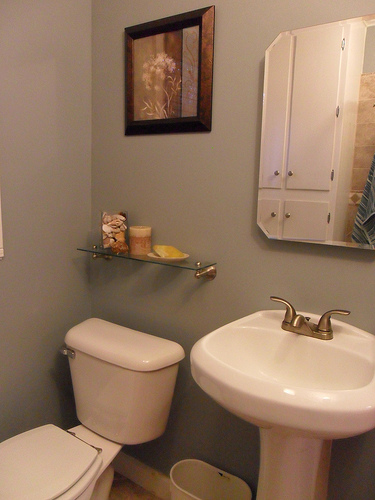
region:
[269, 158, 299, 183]
silver door handle on cabinet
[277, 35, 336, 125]
white cabinet door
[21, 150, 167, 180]
freshly painted white walls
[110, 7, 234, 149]
brown frame on picture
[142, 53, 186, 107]
flowers in the picture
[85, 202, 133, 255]
napkin box on shelf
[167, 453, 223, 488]
white waste basket on ground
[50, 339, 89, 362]
silver handle on toilet bowl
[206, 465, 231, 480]
small black spot on back of waste basket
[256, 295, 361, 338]
gold faucets on porcelain sink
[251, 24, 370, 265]
Mirror on the wall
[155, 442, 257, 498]
Trash can on the floor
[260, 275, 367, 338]
Faucet on the sink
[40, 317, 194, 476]
The toilet is white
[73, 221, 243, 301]
Shelf above the toilet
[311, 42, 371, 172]
Reflection in the mirror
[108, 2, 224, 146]
Picture on the wall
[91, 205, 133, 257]
Shells in a jar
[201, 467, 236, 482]
Stain inside the trash can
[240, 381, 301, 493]
Bottom of the sink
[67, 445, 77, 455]
part of a toilet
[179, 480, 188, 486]
part of a bucket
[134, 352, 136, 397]
edge of a tank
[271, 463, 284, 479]
part of a sink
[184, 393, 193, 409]
edge of a wall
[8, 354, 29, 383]
side of a wall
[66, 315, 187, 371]
The top of the toilet tank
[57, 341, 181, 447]
The toilet tank holds water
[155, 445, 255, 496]
A white trash can on the floor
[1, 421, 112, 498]
The toilet near the wall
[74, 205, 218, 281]
The glass shelf hanging on the wall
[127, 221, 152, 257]
A candle sitting on the shelf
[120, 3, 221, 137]
A picture hanging on the wall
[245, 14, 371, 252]
The mirror hanging on the wall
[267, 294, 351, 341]
A stainless steel faucet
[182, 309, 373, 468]
The sink is white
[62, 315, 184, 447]
a white porcelain toilet tank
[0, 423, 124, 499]
a white porcelain toilet bowl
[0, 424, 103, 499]
a white plastic toilet seat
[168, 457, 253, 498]
a plastic waste basket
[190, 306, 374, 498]
a white porcelain bathroom sink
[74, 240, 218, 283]
a wall mounted glass shelf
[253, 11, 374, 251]
a vanity mirror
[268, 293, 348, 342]
a bathroom faucet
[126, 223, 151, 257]
a brown candle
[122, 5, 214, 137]
a framed mirror print